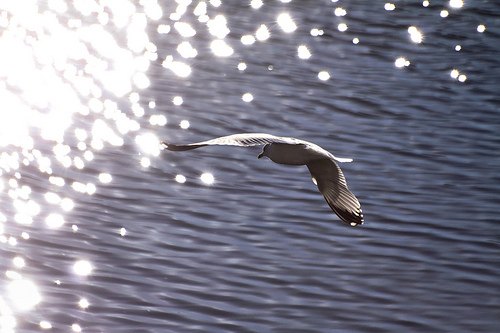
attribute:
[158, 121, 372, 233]
bird — flying, gray, white, soaring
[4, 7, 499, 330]
water — rippled, blue, reflecting, wavy, rippling, spotty, speckled, reflective, relfecting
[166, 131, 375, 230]
wings — tipped, open, white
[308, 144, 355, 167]
tail — white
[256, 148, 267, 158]
beak — black, small, tiny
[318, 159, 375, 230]
feathers — splayed